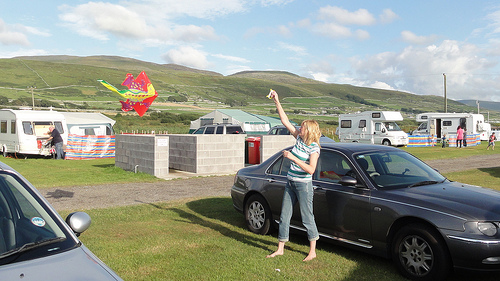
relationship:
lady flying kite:
[265, 88, 322, 260] [96, 71, 157, 113]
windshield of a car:
[357, 155, 435, 185] [226, 139, 498, 276]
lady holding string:
[265, 88, 322, 260] [264, 86, 274, 98]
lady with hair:
[265, 88, 322, 260] [299, 119, 323, 149]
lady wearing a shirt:
[265, 88, 322, 260] [284, 132, 321, 183]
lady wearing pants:
[265, 88, 322, 260] [278, 172, 318, 242]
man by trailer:
[46, 129, 68, 155] [0, 97, 69, 159]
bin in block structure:
[246, 131, 265, 165] [114, 126, 296, 183]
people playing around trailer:
[485, 131, 497, 150] [418, 103, 497, 140]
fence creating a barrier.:
[60, 129, 117, 160] [127, 124, 257, 178]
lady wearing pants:
[265, 88, 322, 260] [278, 179, 320, 242]